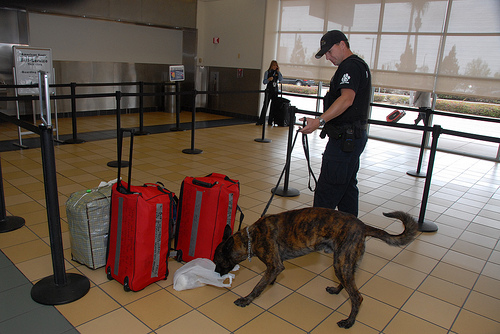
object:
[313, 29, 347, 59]
baseball cap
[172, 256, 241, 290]
bag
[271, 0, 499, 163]
blinds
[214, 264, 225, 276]
nose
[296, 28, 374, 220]
cop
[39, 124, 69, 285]
pole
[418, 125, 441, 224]
pole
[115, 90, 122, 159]
pole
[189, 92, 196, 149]
pole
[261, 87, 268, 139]
pole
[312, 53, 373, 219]
outfit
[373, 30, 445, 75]
window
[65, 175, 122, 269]
bag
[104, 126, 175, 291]
bag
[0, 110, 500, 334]
colored tiles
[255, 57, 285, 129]
passengers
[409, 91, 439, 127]
woman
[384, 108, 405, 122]
suitcase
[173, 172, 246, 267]
bag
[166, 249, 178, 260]
wheel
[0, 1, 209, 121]
wall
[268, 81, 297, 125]
suitcase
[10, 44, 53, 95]
sign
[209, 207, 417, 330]
dog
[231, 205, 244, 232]
handle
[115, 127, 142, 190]
handle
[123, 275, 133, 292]
wheels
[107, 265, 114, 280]
wheels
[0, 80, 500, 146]
divider rope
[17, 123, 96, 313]
pole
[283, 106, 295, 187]
pole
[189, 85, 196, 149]
pole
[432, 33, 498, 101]
window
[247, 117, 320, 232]
leash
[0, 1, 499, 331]
building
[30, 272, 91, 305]
base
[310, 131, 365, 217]
leg